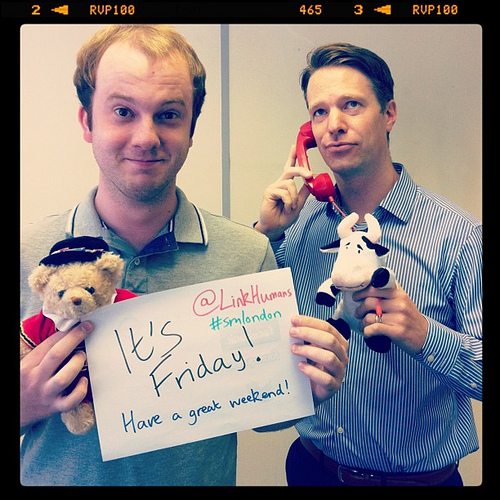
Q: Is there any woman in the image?
A: No, there are no women.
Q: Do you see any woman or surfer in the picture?
A: No, there are no women or surfers.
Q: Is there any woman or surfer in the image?
A: No, there are no women or surfers.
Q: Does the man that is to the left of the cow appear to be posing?
A: Yes, the man is posing.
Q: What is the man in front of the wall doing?
A: The man is posing.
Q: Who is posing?
A: The man is posing.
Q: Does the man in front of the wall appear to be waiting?
A: No, the man is posing.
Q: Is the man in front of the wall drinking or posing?
A: The man is posing.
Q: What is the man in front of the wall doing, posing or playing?
A: The man is posing.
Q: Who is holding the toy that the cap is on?
A: The man is holding the stuffed bear.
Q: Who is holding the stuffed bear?
A: The man is holding the stuffed bear.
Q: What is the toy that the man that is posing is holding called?
A: The toy is a stuffed bear.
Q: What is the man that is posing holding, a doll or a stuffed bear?
A: The man is holding a stuffed bear.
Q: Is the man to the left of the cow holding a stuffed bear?
A: Yes, the man is holding a stuffed bear.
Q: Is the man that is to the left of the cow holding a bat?
A: No, the man is holding a stuffed bear.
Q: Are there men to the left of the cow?
A: Yes, there is a man to the left of the cow.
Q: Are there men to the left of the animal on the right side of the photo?
A: Yes, there is a man to the left of the cow.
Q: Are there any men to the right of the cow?
A: No, the man is to the left of the cow.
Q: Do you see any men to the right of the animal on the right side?
A: No, the man is to the left of the cow.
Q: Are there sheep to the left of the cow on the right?
A: No, there is a man to the left of the cow.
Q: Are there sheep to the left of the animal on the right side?
A: No, there is a man to the left of the cow.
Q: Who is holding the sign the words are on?
A: The man is holding the sign.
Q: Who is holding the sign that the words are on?
A: The man is holding the sign.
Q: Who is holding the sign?
A: The man is holding the sign.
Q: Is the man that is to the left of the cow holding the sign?
A: Yes, the man is holding the sign.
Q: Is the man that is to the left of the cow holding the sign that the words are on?
A: Yes, the man is holding the sign.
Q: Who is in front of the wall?
A: The man is in front of the wall.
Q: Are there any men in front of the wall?
A: Yes, there is a man in front of the wall.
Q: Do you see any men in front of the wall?
A: Yes, there is a man in front of the wall.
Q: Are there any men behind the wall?
A: No, the man is in front of the wall.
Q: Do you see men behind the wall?
A: No, the man is in front of the wall.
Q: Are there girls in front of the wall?
A: No, there is a man in front of the wall.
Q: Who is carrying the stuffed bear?
A: The man is carrying the stuffed bear.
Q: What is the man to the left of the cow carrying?
A: The man is carrying a stuffed bear.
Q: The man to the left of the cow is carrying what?
A: The man is carrying a stuffed bear.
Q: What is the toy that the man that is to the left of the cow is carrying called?
A: The toy is a stuffed bear.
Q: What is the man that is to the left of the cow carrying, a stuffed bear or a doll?
A: The man is carrying a stuffed bear.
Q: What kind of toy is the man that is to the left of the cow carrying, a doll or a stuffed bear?
A: The man is carrying a stuffed bear.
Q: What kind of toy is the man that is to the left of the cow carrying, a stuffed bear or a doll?
A: The man is carrying a stuffed bear.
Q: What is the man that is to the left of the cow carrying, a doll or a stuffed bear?
A: The man is carrying a stuffed bear.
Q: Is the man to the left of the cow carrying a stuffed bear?
A: Yes, the man is carrying a stuffed bear.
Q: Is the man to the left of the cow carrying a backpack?
A: No, the man is carrying a stuffed bear.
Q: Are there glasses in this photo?
A: No, there are no glasses.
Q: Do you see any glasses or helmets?
A: No, there are no glasses or helmets.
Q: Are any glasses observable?
A: No, there are no glasses.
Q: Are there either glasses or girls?
A: No, there are no glasses or girls.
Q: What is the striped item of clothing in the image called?
A: The clothing item is a shirt.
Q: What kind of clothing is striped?
A: The clothing is a shirt.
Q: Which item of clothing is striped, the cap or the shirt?
A: The shirt is striped.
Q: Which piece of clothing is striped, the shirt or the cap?
A: The shirt is striped.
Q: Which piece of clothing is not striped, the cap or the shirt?
A: The cap is not striped.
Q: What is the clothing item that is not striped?
A: The clothing item is a cap.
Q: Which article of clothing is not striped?
A: The clothing item is a cap.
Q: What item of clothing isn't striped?
A: The clothing item is a cap.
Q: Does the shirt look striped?
A: Yes, the shirt is striped.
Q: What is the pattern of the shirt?
A: The shirt is striped.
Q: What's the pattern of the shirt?
A: The shirt is striped.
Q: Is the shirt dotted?
A: No, the shirt is striped.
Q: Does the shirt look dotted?
A: No, the shirt is striped.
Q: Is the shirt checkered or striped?
A: The shirt is striped.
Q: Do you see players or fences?
A: No, there are no fences or players.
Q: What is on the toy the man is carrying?
A: The cap is on the stuffed bear.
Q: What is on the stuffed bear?
A: The cap is on the stuffed bear.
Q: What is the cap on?
A: The cap is on the stuffed bear.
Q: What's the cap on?
A: The cap is on the stuffed bear.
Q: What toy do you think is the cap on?
A: The cap is on the stuffed bear.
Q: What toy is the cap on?
A: The cap is on the stuffed bear.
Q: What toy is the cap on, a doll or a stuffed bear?
A: The cap is on a stuffed bear.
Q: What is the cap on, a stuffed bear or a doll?
A: The cap is on a stuffed bear.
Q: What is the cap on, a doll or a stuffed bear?
A: The cap is on a stuffed bear.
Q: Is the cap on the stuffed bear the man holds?
A: Yes, the cap is on the stuffed bear.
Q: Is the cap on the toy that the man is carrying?
A: Yes, the cap is on the stuffed bear.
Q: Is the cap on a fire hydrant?
A: No, the cap is on the stuffed bear.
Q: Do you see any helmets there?
A: No, there are no helmets.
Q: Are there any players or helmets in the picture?
A: No, there are no helmets or players.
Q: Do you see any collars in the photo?
A: Yes, there is a collar.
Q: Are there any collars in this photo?
A: Yes, there is a collar.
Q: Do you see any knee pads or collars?
A: Yes, there is a collar.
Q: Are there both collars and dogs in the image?
A: No, there is a collar but no dogs.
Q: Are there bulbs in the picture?
A: No, there are no bulbs.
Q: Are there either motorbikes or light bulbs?
A: No, there are no light bulbs or motorbikes.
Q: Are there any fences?
A: No, there are no fences.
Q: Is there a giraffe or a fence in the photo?
A: No, there are no fences or giraffes.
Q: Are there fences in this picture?
A: No, there are no fences.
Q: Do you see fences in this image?
A: No, there are no fences.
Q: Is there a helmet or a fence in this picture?
A: No, there are no fences or helmets.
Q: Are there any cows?
A: Yes, there is a cow.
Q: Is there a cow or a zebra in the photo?
A: Yes, there is a cow.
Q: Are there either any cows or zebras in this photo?
A: Yes, there is a cow.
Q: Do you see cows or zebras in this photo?
A: Yes, there is a cow.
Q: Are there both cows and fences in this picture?
A: No, there is a cow but no fences.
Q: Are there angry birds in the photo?
A: No, there are no angry birds.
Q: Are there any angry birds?
A: No, there are no angry birds.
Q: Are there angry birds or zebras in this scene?
A: No, there are no angry birds or zebras.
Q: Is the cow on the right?
A: Yes, the cow is on the right of the image.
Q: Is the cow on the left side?
A: No, the cow is on the right of the image.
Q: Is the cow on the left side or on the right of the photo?
A: The cow is on the right of the image.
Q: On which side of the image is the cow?
A: The cow is on the right of the image.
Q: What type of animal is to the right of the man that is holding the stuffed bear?
A: The animal is a cow.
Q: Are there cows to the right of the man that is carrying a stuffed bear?
A: Yes, there is a cow to the right of the man.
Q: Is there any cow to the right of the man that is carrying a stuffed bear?
A: Yes, there is a cow to the right of the man.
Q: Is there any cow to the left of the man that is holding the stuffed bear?
A: No, the cow is to the right of the man.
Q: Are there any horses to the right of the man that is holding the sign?
A: No, there is a cow to the right of the man.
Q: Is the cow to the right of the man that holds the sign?
A: Yes, the cow is to the right of the man.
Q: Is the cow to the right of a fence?
A: No, the cow is to the right of the man.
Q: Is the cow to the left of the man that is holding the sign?
A: No, the cow is to the right of the man.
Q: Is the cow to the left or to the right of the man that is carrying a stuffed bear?
A: The cow is to the right of the man.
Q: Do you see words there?
A: Yes, there are words.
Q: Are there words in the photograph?
A: Yes, there are words.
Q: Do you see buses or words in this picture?
A: Yes, there are words.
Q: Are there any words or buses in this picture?
A: Yes, there are words.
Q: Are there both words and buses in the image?
A: No, there are words but no buses.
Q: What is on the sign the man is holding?
A: The words are on the sign.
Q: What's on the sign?
A: The words are on the sign.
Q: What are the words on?
A: The words are on the sign.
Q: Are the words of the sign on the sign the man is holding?
A: Yes, the words are on the sign.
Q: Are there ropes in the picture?
A: No, there are no ropes.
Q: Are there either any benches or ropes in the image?
A: No, there are no ropes or benches.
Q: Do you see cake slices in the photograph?
A: No, there are no cake slices.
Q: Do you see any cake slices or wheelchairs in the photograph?
A: No, there are no cake slices or wheelchairs.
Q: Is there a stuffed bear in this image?
A: Yes, there is a stuffed bear.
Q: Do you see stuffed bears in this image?
A: Yes, there is a stuffed bear.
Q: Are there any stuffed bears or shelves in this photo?
A: Yes, there is a stuffed bear.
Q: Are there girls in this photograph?
A: No, there are no girls.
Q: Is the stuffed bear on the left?
A: Yes, the stuffed bear is on the left of the image.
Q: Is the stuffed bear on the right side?
A: No, the stuffed bear is on the left of the image.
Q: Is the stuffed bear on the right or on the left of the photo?
A: The stuffed bear is on the left of the image.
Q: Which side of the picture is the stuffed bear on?
A: The stuffed bear is on the left of the image.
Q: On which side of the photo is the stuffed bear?
A: The stuffed bear is on the left of the image.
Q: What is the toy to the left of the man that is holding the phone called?
A: The toy is a stuffed bear.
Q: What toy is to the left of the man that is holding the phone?
A: The toy is a stuffed bear.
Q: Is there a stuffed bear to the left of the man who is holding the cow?
A: Yes, there is a stuffed bear to the left of the man.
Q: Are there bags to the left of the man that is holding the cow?
A: No, there is a stuffed bear to the left of the man.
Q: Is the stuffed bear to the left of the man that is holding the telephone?
A: Yes, the stuffed bear is to the left of the man.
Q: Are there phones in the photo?
A: Yes, there is a phone.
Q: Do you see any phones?
A: Yes, there is a phone.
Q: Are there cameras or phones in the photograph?
A: Yes, there is a phone.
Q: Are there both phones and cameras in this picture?
A: No, there is a phone but no cameras.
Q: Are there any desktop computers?
A: No, there are no desktop computers.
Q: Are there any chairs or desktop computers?
A: No, there are no desktop computers or chairs.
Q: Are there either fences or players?
A: No, there are no fences or players.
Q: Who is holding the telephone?
A: The man is holding the telephone.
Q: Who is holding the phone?
A: The man is holding the telephone.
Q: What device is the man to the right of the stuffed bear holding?
A: The man is holding the phone.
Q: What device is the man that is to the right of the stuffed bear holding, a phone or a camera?
A: The man is holding a phone.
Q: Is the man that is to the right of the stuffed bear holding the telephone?
A: Yes, the man is holding the telephone.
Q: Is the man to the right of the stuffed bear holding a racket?
A: No, the man is holding the telephone.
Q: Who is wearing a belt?
A: The man is wearing a belt.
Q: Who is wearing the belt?
A: The man is wearing a belt.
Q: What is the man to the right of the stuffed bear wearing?
A: The man is wearing a belt.